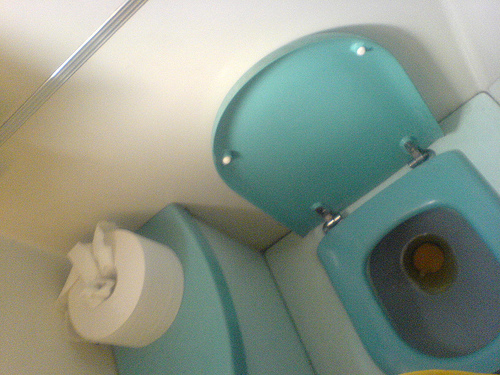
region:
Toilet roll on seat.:
[57, 242, 184, 367]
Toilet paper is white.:
[58, 240, 170, 349]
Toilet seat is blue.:
[139, 215, 221, 362]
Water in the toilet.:
[403, 231, 458, 291]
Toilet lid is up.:
[212, 73, 411, 213]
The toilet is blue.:
[310, 160, 475, 335]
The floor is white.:
[238, 243, 322, 346]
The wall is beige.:
[86, 85, 182, 174]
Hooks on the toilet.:
[306, 195, 363, 240]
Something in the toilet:
[370, 217, 462, 297]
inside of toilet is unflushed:
[398, 230, 462, 296]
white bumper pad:
[217, 152, 236, 170]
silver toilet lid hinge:
[307, 202, 350, 235]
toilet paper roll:
[57, 223, 187, 345]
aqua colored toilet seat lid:
[199, 25, 474, 236]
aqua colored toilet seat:
[309, 150, 499, 370]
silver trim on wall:
[4, 0, 152, 152]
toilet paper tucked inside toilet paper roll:
[56, 225, 131, 300]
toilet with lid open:
[198, 26, 498, 372]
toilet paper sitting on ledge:
[56, 197, 241, 373]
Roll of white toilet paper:
[57, 219, 187, 347]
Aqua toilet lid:
[200, 28, 447, 236]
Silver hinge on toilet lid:
[307, 197, 346, 232]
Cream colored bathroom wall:
[71, 104, 160, 183]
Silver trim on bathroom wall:
[12, 7, 149, 103]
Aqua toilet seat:
[312, 147, 499, 367]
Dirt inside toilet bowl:
[402, 235, 461, 294]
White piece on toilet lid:
[217, 148, 234, 170]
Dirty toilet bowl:
[362, 193, 494, 362]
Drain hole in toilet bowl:
[400, 238, 457, 280]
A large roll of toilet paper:
[56, 231, 195, 349]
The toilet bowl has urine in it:
[319, 183, 495, 363]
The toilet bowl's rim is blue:
[301, 181, 497, 278]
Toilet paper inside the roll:
[69, 228, 129, 312]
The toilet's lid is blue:
[197, 30, 427, 221]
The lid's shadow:
[356, 18, 478, 136]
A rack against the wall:
[31, 33, 113, 136]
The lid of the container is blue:
[187, 241, 316, 373]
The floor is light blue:
[271, 245, 319, 328]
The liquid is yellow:
[403, 233, 456, 293]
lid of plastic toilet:
[208, 29, 445, 243]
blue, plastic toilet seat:
[317, 149, 497, 373]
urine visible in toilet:
[401, 230, 455, 297]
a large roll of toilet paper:
[50, 215, 182, 353]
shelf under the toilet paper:
[111, 200, 316, 372]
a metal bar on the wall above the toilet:
[2, 1, 149, 144]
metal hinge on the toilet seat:
[311, 135, 432, 232]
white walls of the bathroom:
[1, 1, 498, 373]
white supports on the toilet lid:
[219, 45, 366, 167]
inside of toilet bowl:
[363, 205, 498, 360]